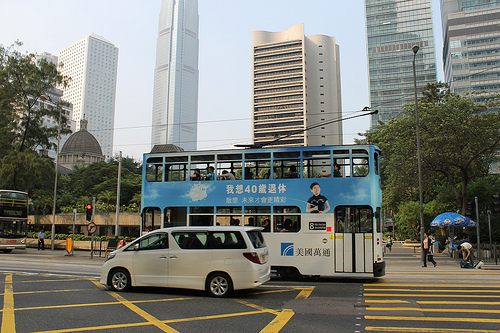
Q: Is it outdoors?
A: Yes, it is outdoors.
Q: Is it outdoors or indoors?
A: It is outdoors.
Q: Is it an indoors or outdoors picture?
A: It is outdoors.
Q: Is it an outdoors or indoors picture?
A: It is outdoors.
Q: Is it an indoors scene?
A: No, it is outdoors.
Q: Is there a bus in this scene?
A: Yes, there is a bus.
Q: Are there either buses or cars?
A: Yes, there is a bus.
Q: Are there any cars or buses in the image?
A: Yes, there is a bus.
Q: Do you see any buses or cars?
A: Yes, there is a bus.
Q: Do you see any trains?
A: No, there are no trains.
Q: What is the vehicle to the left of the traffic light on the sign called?
A: The vehicle is a bus.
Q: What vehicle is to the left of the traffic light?
A: The vehicle is a bus.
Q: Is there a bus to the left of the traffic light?
A: Yes, there is a bus to the left of the traffic light.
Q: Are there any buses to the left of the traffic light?
A: Yes, there is a bus to the left of the traffic light.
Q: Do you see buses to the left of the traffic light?
A: Yes, there is a bus to the left of the traffic light.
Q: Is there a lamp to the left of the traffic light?
A: No, there is a bus to the left of the traffic light.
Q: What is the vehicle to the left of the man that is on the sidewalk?
A: The vehicle is a bus.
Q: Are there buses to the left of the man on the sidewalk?
A: Yes, there is a bus to the left of the man.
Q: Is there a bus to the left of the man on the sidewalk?
A: Yes, there is a bus to the left of the man.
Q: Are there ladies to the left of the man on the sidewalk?
A: No, there is a bus to the left of the man.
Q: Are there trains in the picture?
A: No, there are no trains.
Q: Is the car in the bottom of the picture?
A: Yes, the car is in the bottom of the image.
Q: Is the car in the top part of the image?
A: No, the car is in the bottom of the image.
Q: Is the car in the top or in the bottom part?
A: The car is in the bottom of the image.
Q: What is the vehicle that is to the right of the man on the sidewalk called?
A: The vehicle is a car.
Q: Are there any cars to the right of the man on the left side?
A: Yes, there is a car to the right of the man.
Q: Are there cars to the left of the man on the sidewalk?
A: No, the car is to the right of the man.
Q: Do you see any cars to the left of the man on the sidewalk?
A: No, the car is to the right of the man.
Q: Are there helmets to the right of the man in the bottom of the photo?
A: No, there is a car to the right of the man.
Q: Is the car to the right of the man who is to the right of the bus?
A: Yes, the car is to the right of the man.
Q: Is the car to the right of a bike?
A: No, the car is to the right of the man.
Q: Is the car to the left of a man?
A: No, the car is to the right of a man.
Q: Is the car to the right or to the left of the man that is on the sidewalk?
A: The car is to the right of the man.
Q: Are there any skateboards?
A: No, there are no skateboards.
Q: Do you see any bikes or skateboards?
A: No, there are no skateboards or bikes.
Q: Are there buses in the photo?
A: Yes, there is a bus.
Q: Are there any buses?
A: Yes, there is a bus.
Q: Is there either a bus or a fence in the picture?
A: Yes, there is a bus.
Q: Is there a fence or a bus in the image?
A: Yes, there is a bus.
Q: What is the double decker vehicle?
A: The vehicle is a bus.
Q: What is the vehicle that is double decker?
A: The vehicle is a bus.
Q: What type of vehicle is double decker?
A: The vehicle is a bus.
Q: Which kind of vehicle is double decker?
A: The vehicle is a bus.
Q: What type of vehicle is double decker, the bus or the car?
A: The bus is double decker.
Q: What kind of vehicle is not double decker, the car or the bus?
A: The car is not double decker.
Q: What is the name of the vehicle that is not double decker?
A: The vehicle is a car.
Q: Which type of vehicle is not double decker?
A: The vehicle is a car.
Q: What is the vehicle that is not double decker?
A: The vehicle is a car.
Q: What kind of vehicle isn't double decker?
A: The vehicle is a car.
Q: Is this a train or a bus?
A: This is a bus.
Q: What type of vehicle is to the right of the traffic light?
A: The vehicle is a bus.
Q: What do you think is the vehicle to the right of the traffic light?
A: The vehicle is a bus.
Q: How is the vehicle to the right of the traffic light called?
A: The vehicle is a bus.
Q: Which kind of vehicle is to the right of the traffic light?
A: The vehicle is a bus.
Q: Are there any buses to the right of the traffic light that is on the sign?
A: Yes, there is a bus to the right of the traffic light.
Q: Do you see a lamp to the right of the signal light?
A: No, there is a bus to the right of the signal light.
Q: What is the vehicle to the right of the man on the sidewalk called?
A: The vehicle is a bus.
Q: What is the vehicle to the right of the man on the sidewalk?
A: The vehicle is a bus.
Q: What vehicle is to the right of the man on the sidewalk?
A: The vehicle is a bus.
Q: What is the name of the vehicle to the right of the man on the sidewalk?
A: The vehicle is a bus.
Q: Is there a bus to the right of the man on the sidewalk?
A: Yes, there is a bus to the right of the man.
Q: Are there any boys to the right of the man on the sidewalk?
A: No, there is a bus to the right of the man.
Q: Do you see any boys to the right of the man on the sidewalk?
A: No, there is a bus to the right of the man.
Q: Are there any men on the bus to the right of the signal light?
A: Yes, there is a man on the bus.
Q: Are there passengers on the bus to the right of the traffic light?
A: No, there is a man on the bus.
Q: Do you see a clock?
A: No, there are no clocks.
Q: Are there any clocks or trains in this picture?
A: No, there are no clocks or trains.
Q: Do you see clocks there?
A: No, there are no clocks.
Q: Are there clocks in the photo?
A: No, there are no clocks.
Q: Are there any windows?
A: Yes, there is a window.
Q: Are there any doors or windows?
A: Yes, there is a window.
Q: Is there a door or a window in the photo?
A: Yes, there is a window.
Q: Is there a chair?
A: No, there are no chairs.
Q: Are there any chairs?
A: No, there are no chairs.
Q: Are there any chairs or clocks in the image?
A: No, there are no chairs or clocks.